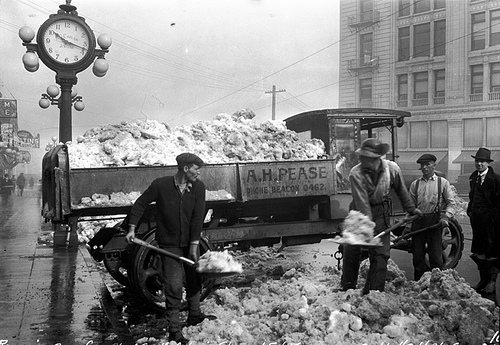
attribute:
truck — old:
[34, 106, 471, 286]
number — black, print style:
[61, 18, 75, 34]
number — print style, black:
[70, 20, 80, 34]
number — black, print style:
[79, 36, 95, 52]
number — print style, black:
[73, 51, 82, 67]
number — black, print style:
[64, 54, 71, 68]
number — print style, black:
[50, 53, 62, 62]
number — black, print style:
[42, 44, 56, 58]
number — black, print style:
[319, 182, 329, 196]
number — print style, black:
[297, 180, 315, 196]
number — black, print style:
[304, 182, 314, 198]